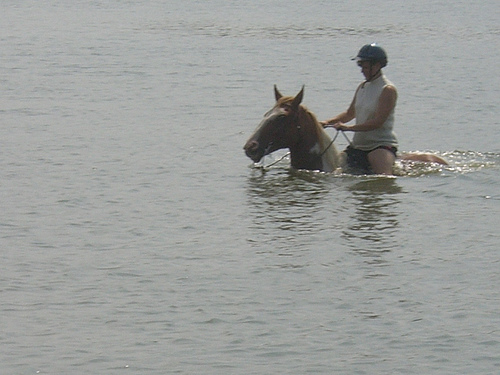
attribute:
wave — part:
[280, 192, 424, 357]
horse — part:
[221, 95, 355, 179]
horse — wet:
[242, 84, 449, 198]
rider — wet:
[312, 37, 403, 180]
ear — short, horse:
[293, 82, 305, 105]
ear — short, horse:
[270, 84, 287, 102]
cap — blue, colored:
[348, 43, 396, 64]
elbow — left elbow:
[340, 82, 404, 146]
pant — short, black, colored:
[346, 144, 398, 165]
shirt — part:
[340, 70, 410, 150]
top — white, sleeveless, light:
[338, 84, 393, 153]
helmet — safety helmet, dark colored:
[350, 43, 389, 62]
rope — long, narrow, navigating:
[306, 117, 355, 164]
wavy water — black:
[248, 149, 471, 256]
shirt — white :
[326, 61, 446, 152]